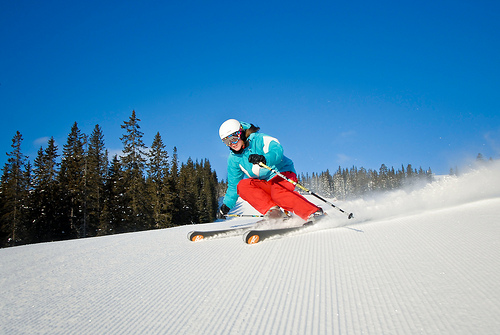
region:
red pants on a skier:
[233, 174, 322, 224]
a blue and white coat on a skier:
[218, 130, 299, 206]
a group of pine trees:
[48, 105, 200, 235]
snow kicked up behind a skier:
[331, 160, 496, 224]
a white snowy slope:
[0, 165, 498, 332]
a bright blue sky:
[2, 2, 495, 171]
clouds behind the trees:
[36, 132, 169, 165]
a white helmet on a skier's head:
[216, 118, 240, 134]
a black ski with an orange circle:
[241, 217, 320, 246]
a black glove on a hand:
[246, 149, 272, 168]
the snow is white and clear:
[153, 219, 230, 315]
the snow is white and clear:
[137, 176, 259, 328]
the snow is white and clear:
[22, 76, 275, 321]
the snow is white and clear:
[79, 123, 199, 330]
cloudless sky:
[0, 0, 492, 113]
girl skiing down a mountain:
[167, 110, 362, 246]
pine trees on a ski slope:
[0, 96, 216, 252]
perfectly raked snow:
[0, 247, 490, 332]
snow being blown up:
[250, 143, 497, 235]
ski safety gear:
[191, 112, 261, 162]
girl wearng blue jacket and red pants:
[197, 118, 337, 223]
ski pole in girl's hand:
[238, 153, 363, 223]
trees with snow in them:
[290, 147, 456, 199]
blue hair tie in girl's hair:
[233, 118, 262, 140]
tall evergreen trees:
[5, 117, 215, 222]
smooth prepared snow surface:
[33, 245, 438, 322]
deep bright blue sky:
[22, 18, 364, 105]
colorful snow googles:
[215, 131, 252, 148]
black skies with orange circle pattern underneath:
[180, 219, 352, 251]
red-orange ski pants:
[231, 169, 321, 220]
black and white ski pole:
[252, 156, 356, 223]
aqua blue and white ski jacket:
[221, 140, 307, 180]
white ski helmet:
[211, 116, 243, 138]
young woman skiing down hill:
[187, 116, 373, 249]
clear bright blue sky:
[0, 0, 498, 185]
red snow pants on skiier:
[244, 173, 319, 225]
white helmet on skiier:
[217, 120, 238, 133]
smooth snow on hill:
[3, 210, 492, 333]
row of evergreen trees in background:
[7, 123, 213, 222]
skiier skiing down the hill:
[218, 120, 329, 241]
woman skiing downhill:
[218, 128, 291, 202]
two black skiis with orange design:
[185, 226, 327, 238]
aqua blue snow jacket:
[222, 132, 283, 185]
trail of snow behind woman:
[326, 152, 498, 221]